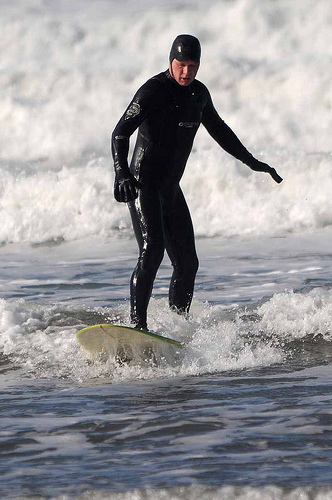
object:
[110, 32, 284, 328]
man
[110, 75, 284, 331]
wet suit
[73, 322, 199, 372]
surf board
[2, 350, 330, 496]
water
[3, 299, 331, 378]
waves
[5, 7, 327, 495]
ocean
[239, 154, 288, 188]
gloves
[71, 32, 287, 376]
surfing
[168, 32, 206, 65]
hat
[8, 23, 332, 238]
waves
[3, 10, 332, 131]
background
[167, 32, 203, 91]
head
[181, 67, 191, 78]
nose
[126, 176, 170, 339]
legs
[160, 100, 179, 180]
black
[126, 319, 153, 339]
feet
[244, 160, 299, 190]
hand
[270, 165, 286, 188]
fingers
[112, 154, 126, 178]
label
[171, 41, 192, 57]
label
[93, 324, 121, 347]
line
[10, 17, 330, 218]
large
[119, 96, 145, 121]
symbol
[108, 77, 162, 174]
arm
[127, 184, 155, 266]
shine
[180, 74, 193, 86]
lips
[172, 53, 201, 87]
face